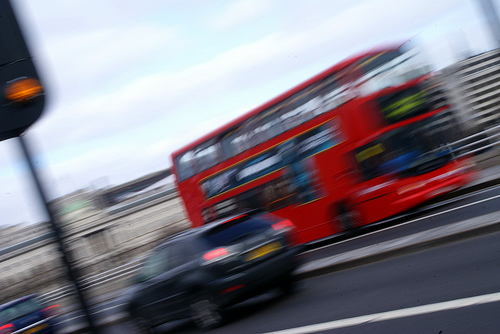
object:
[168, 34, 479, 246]
bus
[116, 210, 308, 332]
car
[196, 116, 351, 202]
sign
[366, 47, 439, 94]
window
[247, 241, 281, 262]
license plate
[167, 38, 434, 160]
top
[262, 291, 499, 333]
line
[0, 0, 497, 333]
photo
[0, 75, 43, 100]
light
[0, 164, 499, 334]
traffic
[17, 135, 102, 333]
pole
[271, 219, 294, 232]
brake lights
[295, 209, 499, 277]
median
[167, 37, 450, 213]
top level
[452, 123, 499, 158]
fencing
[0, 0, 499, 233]
sky